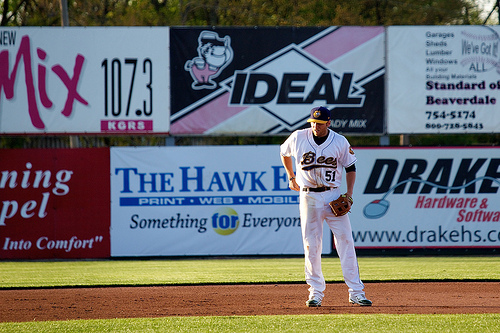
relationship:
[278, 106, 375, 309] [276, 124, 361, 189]
player with jersey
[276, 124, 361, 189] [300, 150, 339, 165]
jersey says bees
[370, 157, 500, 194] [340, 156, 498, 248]
drake on banner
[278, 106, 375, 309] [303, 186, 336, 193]
player has belt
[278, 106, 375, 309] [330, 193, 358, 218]
player has glove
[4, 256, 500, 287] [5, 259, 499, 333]
grass of field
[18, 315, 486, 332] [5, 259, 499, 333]
grass of field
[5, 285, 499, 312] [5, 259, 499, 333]
dirt on field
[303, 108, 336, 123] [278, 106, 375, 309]
cap worn by player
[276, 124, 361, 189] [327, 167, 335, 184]
jersey has 51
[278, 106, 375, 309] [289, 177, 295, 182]
player has watch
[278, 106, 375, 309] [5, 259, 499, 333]
player on field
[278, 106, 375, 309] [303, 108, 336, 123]
player wears cap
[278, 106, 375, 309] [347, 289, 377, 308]
player has shoes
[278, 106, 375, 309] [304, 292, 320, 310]
player has shoes